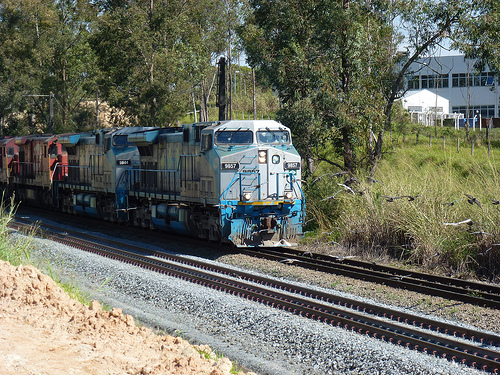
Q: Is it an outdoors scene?
A: Yes, it is outdoors.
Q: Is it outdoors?
A: Yes, it is outdoors.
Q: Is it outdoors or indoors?
A: It is outdoors.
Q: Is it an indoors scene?
A: No, it is outdoors.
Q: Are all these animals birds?
A: Yes, all the animals are birds.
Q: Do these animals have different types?
A: No, all the animals are birds.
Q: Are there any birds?
A: Yes, there is a bird.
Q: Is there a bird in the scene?
A: Yes, there is a bird.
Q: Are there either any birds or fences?
A: Yes, there is a bird.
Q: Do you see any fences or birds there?
A: Yes, there is a bird.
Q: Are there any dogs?
A: No, there are no dogs.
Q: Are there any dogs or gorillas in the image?
A: No, there are no dogs or gorillas.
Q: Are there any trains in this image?
A: Yes, there is a train.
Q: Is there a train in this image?
A: Yes, there is a train.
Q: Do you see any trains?
A: Yes, there is a train.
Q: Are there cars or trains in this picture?
A: Yes, there is a train.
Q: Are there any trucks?
A: No, there are no trucks.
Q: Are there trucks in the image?
A: No, there are no trucks.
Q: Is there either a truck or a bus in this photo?
A: No, there are no trucks or buses.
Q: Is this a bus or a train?
A: This is a train.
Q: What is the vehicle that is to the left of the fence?
A: The vehicle is a train.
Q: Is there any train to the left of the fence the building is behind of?
A: Yes, there is a train to the left of the fence.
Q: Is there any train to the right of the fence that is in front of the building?
A: No, the train is to the left of the fence.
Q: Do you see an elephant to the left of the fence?
A: No, there is a train to the left of the fence.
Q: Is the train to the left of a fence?
A: Yes, the train is to the left of a fence.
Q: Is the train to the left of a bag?
A: No, the train is to the left of a fence.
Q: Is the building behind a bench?
A: No, the building is behind a fence.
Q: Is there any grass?
A: Yes, there is grass.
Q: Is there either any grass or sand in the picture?
A: Yes, there is grass.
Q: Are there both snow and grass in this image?
A: No, there is grass but no snow.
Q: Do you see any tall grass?
A: Yes, there is tall grass.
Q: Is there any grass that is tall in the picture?
A: Yes, there is tall grass.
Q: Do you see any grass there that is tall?
A: Yes, there is grass that is tall.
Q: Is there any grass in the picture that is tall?
A: Yes, there is grass that is tall.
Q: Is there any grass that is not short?
A: Yes, there is tall grass.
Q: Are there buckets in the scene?
A: No, there are no buckets.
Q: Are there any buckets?
A: No, there are no buckets.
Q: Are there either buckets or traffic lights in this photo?
A: No, there are no buckets or traffic lights.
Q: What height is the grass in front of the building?
A: The grass is tall.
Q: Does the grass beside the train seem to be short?
A: No, the grass is tall.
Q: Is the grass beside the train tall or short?
A: The grass is tall.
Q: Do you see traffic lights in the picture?
A: No, there are no traffic lights.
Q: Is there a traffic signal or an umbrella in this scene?
A: No, there are no traffic lights or umbrellas.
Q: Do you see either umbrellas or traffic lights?
A: No, there are no traffic lights or umbrellas.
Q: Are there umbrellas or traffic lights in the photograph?
A: No, there are no traffic lights or umbrellas.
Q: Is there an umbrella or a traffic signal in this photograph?
A: No, there are no traffic lights or umbrellas.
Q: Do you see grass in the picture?
A: Yes, there is grass.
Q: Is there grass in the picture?
A: Yes, there is grass.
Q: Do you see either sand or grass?
A: Yes, there is grass.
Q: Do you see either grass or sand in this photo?
A: Yes, there is grass.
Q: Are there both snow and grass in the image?
A: No, there is grass but no snow.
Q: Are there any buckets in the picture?
A: No, there are no buckets.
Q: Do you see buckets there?
A: No, there are no buckets.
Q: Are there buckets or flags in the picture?
A: No, there are no buckets or flags.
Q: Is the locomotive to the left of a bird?
A: Yes, the locomotive is to the left of a bird.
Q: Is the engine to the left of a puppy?
A: No, the engine is to the left of a bird.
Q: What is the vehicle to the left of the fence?
A: The vehicle is a locomotive.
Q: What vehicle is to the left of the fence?
A: The vehicle is a locomotive.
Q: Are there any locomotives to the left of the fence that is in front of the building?
A: Yes, there is a locomotive to the left of the fence.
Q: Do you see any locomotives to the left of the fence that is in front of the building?
A: Yes, there is a locomotive to the left of the fence.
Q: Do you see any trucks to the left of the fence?
A: No, there is a locomotive to the left of the fence.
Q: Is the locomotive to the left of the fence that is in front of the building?
A: Yes, the locomotive is to the left of the fence.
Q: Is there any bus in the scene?
A: No, there are no buses.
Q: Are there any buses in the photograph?
A: No, there are no buses.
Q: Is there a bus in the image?
A: No, there are no buses.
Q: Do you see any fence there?
A: Yes, there is a fence.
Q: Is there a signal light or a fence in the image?
A: Yes, there is a fence.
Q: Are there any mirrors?
A: No, there are no mirrors.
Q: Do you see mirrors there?
A: No, there are no mirrors.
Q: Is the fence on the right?
A: Yes, the fence is on the right of the image.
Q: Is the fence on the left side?
A: No, the fence is on the right of the image.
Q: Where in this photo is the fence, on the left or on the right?
A: The fence is on the right of the image.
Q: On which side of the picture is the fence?
A: The fence is on the right of the image.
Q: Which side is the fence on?
A: The fence is on the right of the image.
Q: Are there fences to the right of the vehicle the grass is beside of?
A: Yes, there is a fence to the right of the train.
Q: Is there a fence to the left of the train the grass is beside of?
A: No, the fence is to the right of the train.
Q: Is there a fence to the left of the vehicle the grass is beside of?
A: No, the fence is to the right of the train.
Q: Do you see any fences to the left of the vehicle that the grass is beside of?
A: No, the fence is to the right of the train.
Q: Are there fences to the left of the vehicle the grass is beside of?
A: No, the fence is to the right of the train.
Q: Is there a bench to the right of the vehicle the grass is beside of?
A: No, there is a fence to the right of the train.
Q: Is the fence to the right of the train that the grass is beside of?
A: Yes, the fence is to the right of the train.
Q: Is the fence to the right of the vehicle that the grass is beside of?
A: Yes, the fence is to the right of the train.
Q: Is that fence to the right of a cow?
A: No, the fence is to the right of the train.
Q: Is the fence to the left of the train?
A: No, the fence is to the right of the train.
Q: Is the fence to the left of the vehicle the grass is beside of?
A: No, the fence is to the right of the train.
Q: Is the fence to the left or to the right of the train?
A: The fence is to the right of the train.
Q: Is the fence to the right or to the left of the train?
A: The fence is to the right of the train.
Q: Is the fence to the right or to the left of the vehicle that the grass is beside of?
A: The fence is to the right of the train.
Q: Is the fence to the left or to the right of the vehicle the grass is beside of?
A: The fence is to the right of the train.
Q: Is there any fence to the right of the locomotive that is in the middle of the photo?
A: Yes, there is a fence to the right of the train engine.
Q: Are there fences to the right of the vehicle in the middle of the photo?
A: Yes, there is a fence to the right of the train engine.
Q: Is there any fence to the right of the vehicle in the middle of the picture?
A: Yes, there is a fence to the right of the train engine.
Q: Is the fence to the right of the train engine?
A: Yes, the fence is to the right of the train engine.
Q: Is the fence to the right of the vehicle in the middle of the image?
A: Yes, the fence is to the right of the train engine.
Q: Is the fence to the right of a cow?
A: No, the fence is to the right of the train engine.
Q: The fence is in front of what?
A: The fence is in front of the building.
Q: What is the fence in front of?
A: The fence is in front of the building.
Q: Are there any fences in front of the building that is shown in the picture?
A: Yes, there is a fence in front of the building.